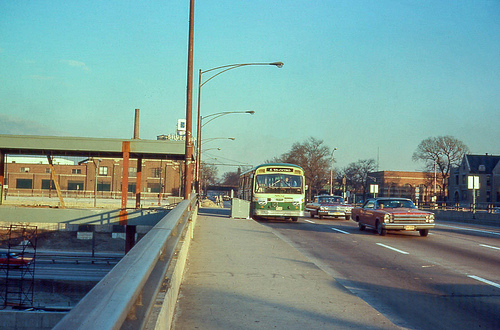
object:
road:
[0, 244, 132, 283]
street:
[252, 209, 499, 329]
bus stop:
[201, 184, 239, 201]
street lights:
[267, 60, 287, 69]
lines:
[372, 241, 411, 256]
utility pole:
[182, 0, 200, 200]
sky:
[0, 0, 499, 186]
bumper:
[382, 223, 437, 231]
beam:
[116, 139, 131, 227]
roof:
[0, 133, 190, 156]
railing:
[48, 192, 203, 330]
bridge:
[48, 192, 500, 330]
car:
[348, 196, 436, 238]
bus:
[238, 162, 308, 222]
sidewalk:
[170, 200, 409, 329]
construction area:
[198, 194, 225, 209]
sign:
[175, 117, 187, 132]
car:
[0, 251, 35, 270]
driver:
[285, 175, 298, 188]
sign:
[466, 173, 481, 190]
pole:
[471, 173, 477, 220]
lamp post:
[194, 67, 203, 196]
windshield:
[254, 173, 304, 195]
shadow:
[325, 275, 500, 328]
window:
[66, 179, 85, 193]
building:
[0, 132, 201, 202]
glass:
[21, 182, 28, 187]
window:
[14, 177, 35, 191]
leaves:
[306, 151, 317, 163]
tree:
[409, 134, 473, 205]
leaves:
[422, 140, 435, 151]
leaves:
[350, 174, 363, 185]